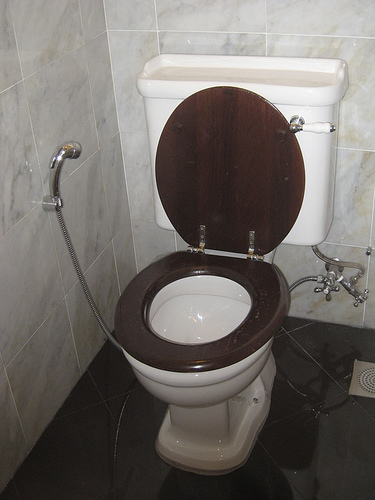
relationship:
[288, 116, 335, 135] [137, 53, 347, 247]
handle on tank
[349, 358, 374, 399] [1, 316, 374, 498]
drain in floor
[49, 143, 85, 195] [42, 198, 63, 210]
spray nozzle in holder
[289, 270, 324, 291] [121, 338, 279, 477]
pipe behind toilet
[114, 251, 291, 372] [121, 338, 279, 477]
seat on bowl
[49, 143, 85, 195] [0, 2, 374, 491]
spray nozzle hooked to wall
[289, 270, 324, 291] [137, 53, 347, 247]
pipe behind tank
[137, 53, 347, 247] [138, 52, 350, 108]
tank has a lid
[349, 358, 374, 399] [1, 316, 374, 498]
drain on floor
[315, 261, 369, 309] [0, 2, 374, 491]
knobs are on wall